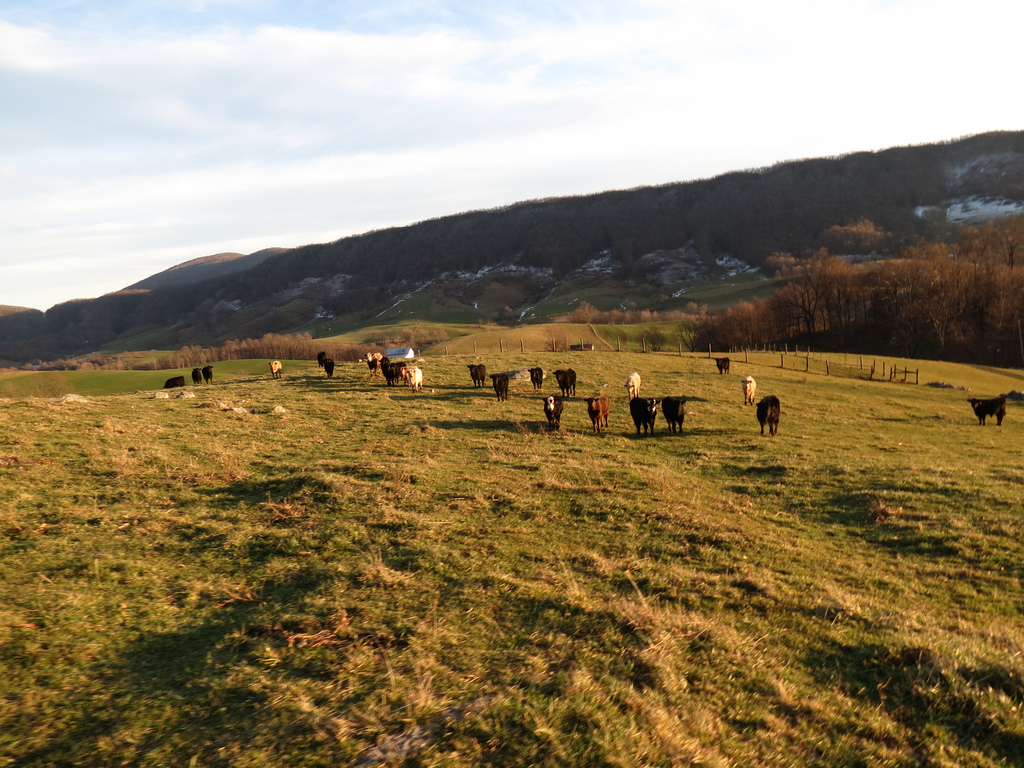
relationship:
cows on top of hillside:
[519, 367, 657, 422] [636, 349, 679, 374]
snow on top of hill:
[516, 267, 546, 281] [504, 200, 634, 305]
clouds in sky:
[362, 49, 452, 123] [165, 11, 194, 23]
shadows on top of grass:
[238, 477, 316, 513] [261, 469, 332, 499]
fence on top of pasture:
[750, 342, 801, 372] [301, 394, 362, 420]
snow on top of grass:
[516, 267, 546, 281] [261, 469, 332, 499]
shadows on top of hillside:
[238, 477, 316, 513] [636, 349, 679, 374]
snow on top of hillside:
[516, 267, 546, 281] [636, 349, 679, 374]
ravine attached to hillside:
[367, 302, 395, 319] [636, 349, 679, 374]